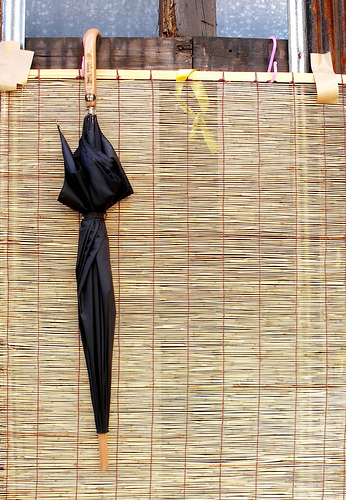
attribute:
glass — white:
[25, 1, 288, 39]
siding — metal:
[0, 0, 28, 57]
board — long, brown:
[25, 32, 293, 78]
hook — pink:
[80, 24, 100, 108]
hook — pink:
[265, 32, 278, 84]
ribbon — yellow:
[168, 56, 258, 195]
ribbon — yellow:
[173, 65, 222, 152]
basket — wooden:
[0, 40, 345, 498]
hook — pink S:
[251, 28, 291, 95]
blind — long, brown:
[1, 67, 337, 495]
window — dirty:
[28, 8, 303, 36]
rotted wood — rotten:
[158, 0, 182, 36]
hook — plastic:
[263, 32, 280, 85]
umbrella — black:
[66, 28, 128, 472]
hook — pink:
[266, 35, 281, 90]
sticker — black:
[82, 91, 98, 101]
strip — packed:
[296, 45, 334, 121]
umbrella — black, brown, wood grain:
[55, 28, 135, 472]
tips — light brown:
[96, 434, 115, 474]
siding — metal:
[287, 1, 307, 73]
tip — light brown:
[95, 431, 111, 475]